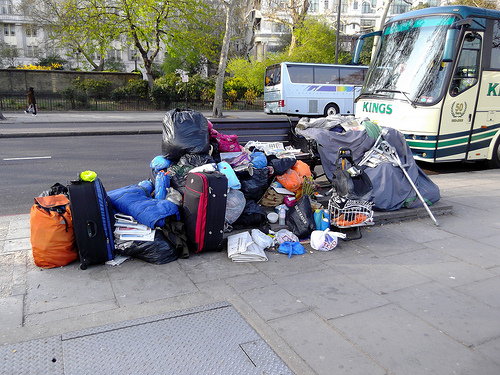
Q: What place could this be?
A: It is a sidewalk.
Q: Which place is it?
A: It is a sidewalk.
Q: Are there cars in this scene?
A: No, there are no cars.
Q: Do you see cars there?
A: No, there are no cars.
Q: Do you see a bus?
A: Yes, there is a bus.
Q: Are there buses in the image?
A: Yes, there is a bus.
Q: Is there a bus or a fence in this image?
A: Yes, there is a bus.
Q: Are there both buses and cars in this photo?
A: No, there is a bus but no cars.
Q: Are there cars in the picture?
A: No, there are no cars.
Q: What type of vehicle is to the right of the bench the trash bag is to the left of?
A: The vehicle is a bus.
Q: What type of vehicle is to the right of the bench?
A: The vehicle is a bus.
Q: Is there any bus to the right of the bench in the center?
A: Yes, there is a bus to the right of the bench.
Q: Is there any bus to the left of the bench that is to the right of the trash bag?
A: No, the bus is to the right of the bench.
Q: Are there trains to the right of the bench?
A: No, there is a bus to the right of the bench.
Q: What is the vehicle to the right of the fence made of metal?
A: The vehicle is a bus.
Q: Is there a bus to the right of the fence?
A: Yes, there is a bus to the right of the fence.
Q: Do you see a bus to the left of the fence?
A: No, the bus is to the right of the fence.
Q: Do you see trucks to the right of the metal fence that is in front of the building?
A: No, there is a bus to the right of the fence.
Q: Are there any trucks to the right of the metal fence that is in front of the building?
A: No, there is a bus to the right of the fence.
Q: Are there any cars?
A: No, there are no cars.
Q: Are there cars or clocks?
A: No, there are no cars or clocks.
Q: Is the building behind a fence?
A: Yes, the building is behind a fence.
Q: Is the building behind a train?
A: No, the building is behind a fence.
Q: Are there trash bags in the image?
A: Yes, there is a trash bag.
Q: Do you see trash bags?
A: Yes, there is a trash bag.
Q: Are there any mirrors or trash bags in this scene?
A: Yes, there is a trash bag.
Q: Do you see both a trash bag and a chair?
A: No, there is a trash bag but no chairs.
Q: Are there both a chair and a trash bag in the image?
A: No, there is a trash bag but no chairs.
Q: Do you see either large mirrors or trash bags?
A: Yes, there is a large trash bag.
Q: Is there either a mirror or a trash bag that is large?
A: Yes, the trash bag is large.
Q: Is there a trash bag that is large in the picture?
A: Yes, there is a large trash bag.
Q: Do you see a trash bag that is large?
A: Yes, there is a trash bag that is large.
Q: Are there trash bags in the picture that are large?
A: Yes, there is a trash bag that is large.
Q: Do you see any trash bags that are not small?
A: Yes, there is a large trash bag.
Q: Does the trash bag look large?
A: Yes, the trash bag is large.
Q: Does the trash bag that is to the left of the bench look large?
A: Yes, the trash bag is large.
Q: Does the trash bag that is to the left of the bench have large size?
A: Yes, the trash bag is large.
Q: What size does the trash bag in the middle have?
A: The trash bag has large size.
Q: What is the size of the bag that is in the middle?
A: The trash bag is large.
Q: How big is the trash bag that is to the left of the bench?
A: The trash bag is large.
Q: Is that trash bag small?
A: No, the trash bag is large.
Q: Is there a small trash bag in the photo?
A: No, there is a trash bag but it is large.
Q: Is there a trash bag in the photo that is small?
A: No, there is a trash bag but it is large.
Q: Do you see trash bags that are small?
A: No, there is a trash bag but it is large.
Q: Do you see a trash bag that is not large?
A: No, there is a trash bag but it is large.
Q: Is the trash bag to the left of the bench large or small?
A: The trash bag is large.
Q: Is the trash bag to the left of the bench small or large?
A: The trash bag is large.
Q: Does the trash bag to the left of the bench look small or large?
A: The trash bag is large.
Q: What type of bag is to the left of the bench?
A: The bag is a trash bag.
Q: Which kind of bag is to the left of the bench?
A: The bag is a trash bag.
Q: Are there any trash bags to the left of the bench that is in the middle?
A: Yes, there is a trash bag to the left of the bench.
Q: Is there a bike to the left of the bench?
A: No, there is a trash bag to the left of the bench.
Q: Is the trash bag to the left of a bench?
A: Yes, the trash bag is to the left of a bench.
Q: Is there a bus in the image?
A: Yes, there is a bus.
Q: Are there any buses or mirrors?
A: Yes, there is a bus.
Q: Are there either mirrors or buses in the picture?
A: Yes, there is a bus.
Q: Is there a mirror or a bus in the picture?
A: Yes, there is a bus.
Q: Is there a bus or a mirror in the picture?
A: Yes, there is a bus.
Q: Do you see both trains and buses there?
A: No, there is a bus but no trains.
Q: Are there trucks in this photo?
A: No, there are no trucks.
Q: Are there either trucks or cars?
A: No, there are no trucks or cars.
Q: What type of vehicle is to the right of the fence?
A: The vehicle is a bus.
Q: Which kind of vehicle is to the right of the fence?
A: The vehicle is a bus.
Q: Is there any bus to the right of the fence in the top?
A: Yes, there is a bus to the right of the fence.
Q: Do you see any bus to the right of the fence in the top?
A: Yes, there is a bus to the right of the fence.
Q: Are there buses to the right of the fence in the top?
A: Yes, there is a bus to the right of the fence.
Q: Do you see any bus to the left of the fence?
A: No, the bus is to the right of the fence.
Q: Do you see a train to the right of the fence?
A: No, there is a bus to the right of the fence.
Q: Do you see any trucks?
A: No, there are no trucks.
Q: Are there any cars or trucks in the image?
A: No, there are no trucks or cars.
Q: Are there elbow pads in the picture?
A: No, there are no elbow pads.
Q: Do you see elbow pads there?
A: No, there are no elbow pads.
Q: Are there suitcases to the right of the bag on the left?
A: Yes, there is a suitcase to the right of the bag.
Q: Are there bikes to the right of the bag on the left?
A: No, there is a suitcase to the right of the bag.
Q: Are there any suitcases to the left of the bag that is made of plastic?
A: Yes, there is a suitcase to the left of the bag.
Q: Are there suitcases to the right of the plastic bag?
A: No, the suitcase is to the left of the bag.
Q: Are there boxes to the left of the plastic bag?
A: No, there is a suitcase to the left of the bag.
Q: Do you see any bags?
A: Yes, there is a bag.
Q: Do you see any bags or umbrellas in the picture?
A: Yes, there is a bag.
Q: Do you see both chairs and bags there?
A: No, there is a bag but no chairs.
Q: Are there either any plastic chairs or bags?
A: Yes, there is a plastic bag.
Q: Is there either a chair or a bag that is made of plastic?
A: Yes, the bag is made of plastic.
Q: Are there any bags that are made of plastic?
A: Yes, there is a bag that is made of plastic.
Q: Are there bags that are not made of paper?
A: Yes, there is a bag that is made of plastic.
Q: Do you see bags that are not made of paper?
A: Yes, there is a bag that is made of plastic.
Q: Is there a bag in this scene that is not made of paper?
A: Yes, there is a bag that is made of plastic.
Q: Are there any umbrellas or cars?
A: No, there are no cars or umbrellas.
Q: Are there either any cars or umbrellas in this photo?
A: No, there are no cars or umbrellas.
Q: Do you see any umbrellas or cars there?
A: No, there are no cars or umbrellas.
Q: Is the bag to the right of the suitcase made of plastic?
A: Yes, the bag is made of plastic.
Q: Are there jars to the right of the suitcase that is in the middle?
A: No, there is a bag to the right of the suitcase.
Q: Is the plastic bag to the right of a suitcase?
A: Yes, the bag is to the right of a suitcase.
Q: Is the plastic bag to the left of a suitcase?
A: No, the bag is to the right of a suitcase.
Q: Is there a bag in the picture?
A: Yes, there is a bag.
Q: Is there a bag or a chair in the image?
A: Yes, there is a bag.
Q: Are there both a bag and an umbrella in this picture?
A: No, there is a bag but no umbrellas.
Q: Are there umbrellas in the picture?
A: No, there are no umbrellas.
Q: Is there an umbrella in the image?
A: No, there are no umbrellas.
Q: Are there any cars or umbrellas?
A: No, there are no umbrellas or cars.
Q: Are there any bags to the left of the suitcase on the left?
A: Yes, there is a bag to the left of the suitcase.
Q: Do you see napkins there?
A: No, there are no napkins.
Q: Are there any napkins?
A: No, there are no napkins.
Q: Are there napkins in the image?
A: No, there are no napkins.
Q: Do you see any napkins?
A: No, there are no napkins.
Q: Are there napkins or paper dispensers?
A: No, there are no napkins or paper dispensers.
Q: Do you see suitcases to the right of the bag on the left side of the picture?
A: Yes, there is a suitcase to the right of the bag.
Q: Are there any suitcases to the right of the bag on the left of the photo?
A: Yes, there is a suitcase to the right of the bag.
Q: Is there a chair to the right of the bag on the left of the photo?
A: No, there is a suitcase to the right of the bag.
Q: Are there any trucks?
A: No, there are no trucks.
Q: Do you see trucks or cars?
A: No, there are no trucks or cars.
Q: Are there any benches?
A: Yes, there is a bench.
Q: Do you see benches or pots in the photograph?
A: Yes, there is a bench.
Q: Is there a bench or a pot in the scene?
A: Yes, there is a bench.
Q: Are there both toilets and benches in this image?
A: No, there is a bench but no toilets.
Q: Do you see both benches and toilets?
A: No, there is a bench but no toilets.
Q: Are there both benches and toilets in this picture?
A: No, there is a bench but no toilets.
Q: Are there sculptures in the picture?
A: No, there are no sculptures.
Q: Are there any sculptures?
A: No, there are no sculptures.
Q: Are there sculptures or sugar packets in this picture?
A: No, there are no sculptures or sugar packets.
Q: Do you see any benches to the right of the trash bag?
A: Yes, there is a bench to the right of the trash bag.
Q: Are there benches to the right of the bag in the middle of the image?
A: Yes, there is a bench to the right of the trash bag.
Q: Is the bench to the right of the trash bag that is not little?
A: Yes, the bench is to the right of the trash bag.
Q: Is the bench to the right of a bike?
A: No, the bench is to the right of the trash bag.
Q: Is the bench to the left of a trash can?
A: No, the bench is to the left of the bus.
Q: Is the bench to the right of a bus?
A: No, the bench is to the left of a bus.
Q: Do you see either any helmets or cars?
A: No, there are no cars or helmets.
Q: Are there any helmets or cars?
A: No, there are no cars or helmets.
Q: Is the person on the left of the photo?
A: Yes, the person is on the left of the image.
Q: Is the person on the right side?
A: No, the person is on the left of the image.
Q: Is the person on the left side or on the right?
A: The person is on the left of the image.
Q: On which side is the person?
A: The person is on the left of the image.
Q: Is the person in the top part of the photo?
A: Yes, the person is in the top of the image.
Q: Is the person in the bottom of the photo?
A: No, the person is in the top of the image.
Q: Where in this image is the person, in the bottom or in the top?
A: The person is in the top of the image.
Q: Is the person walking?
A: Yes, the person is walking.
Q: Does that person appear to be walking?
A: Yes, the person is walking.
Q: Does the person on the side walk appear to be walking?
A: Yes, the person is walking.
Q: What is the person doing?
A: The person is walking.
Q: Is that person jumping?
A: No, the person is walking.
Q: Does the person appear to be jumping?
A: No, the person is walking.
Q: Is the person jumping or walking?
A: The person is walking.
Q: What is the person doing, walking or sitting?
A: The person is walking.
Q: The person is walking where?
A: The person is walking on the sidewalk.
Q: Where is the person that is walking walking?
A: The person is walking on the sidewalk.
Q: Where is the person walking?
A: The person is walking on the sidewalk.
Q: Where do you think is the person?
A: The person is on the sidewalk.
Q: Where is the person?
A: The person is on the sidewalk.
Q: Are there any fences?
A: Yes, there is a fence.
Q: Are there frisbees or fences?
A: Yes, there is a fence.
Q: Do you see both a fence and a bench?
A: Yes, there are both a fence and a bench.